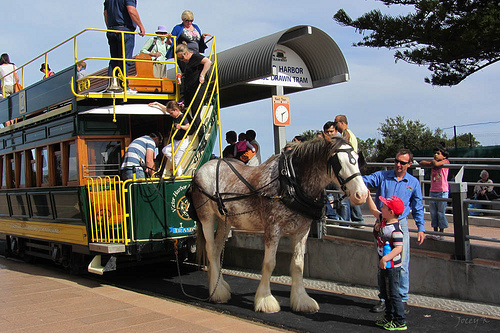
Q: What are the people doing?
A: Descending.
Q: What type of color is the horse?
A: White and brown.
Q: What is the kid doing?
A: Petting a horse.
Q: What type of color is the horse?
A: Brown.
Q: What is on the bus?
A: Stairs.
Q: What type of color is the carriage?
A: Green and yellow.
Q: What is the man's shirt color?
A: Blue.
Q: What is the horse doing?
A: Pulling a trailer.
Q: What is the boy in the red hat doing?
A: Petting the horse.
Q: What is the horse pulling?
A: A tram.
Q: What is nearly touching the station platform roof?
A: Tree branches.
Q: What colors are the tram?
A: Green and yellow.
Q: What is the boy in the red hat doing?
A: Petting the horse.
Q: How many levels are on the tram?
A: Two.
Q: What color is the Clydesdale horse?
A: Gray.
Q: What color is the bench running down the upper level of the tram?
A: Brown.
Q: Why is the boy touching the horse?
A: To pet him.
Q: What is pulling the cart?
A: The horse.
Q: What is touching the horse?
A: The boy.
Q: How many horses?
A: 1.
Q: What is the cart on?
A: The street.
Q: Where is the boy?
A: In front of the horse.